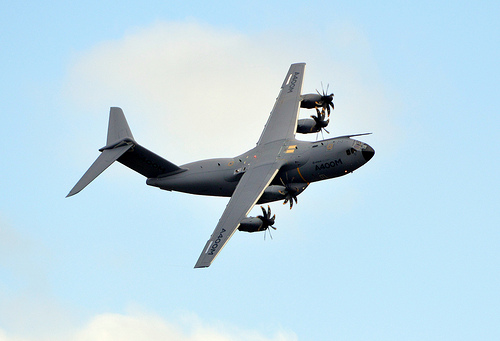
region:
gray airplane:
[72, 32, 379, 293]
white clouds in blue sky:
[21, 16, 105, 70]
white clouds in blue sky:
[4, 88, 64, 125]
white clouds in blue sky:
[24, 221, 104, 262]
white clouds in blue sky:
[87, 206, 161, 261]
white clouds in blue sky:
[70, 273, 172, 327]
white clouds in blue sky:
[227, 261, 324, 328]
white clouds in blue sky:
[324, 281, 372, 313]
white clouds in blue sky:
[362, 238, 454, 319]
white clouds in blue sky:
[324, 193, 424, 244]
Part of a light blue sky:
[10, 288, 51, 338]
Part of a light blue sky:
[68, 280, 105, 330]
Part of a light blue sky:
[156, 279, 202, 337]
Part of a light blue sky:
[226, 291, 296, 326]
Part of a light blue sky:
[305, 274, 352, 338]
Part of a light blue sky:
[359, 264, 404, 310]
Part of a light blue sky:
[421, 266, 478, 338]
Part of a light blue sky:
[396, 213, 466, 260]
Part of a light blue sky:
[319, 204, 379, 262]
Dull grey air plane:
[68, 53, 368, 293]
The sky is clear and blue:
[374, 25, 487, 314]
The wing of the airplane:
[191, 166, 283, 271]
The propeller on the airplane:
[259, 200, 282, 237]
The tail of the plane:
[54, 95, 181, 198]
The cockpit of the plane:
[339, 136, 365, 156]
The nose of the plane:
[335, 131, 379, 171]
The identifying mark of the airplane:
[203, 223, 230, 260]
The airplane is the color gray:
[43, 60, 369, 275]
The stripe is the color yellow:
[291, 163, 316, 195]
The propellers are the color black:
[313, 75, 343, 140]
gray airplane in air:
[82, 60, 388, 284]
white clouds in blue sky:
[15, 148, 43, 196]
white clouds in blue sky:
[286, 253, 342, 303]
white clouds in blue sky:
[349, 265, 416, 312]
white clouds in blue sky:
[402, 51, 447, 104]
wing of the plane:
[171, 175, 274, 294]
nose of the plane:
[342, 135, 381, 178]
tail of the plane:
[77, 107, 179, 192]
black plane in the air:
[136, 87, 423, 268]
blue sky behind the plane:
[373, 134, 454, 232]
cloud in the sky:
[153, 17, 249, 92]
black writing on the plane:
[303, 150, 352, 181]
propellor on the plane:
[246, 201, 284, 248]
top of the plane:
[223, 136, 293, 171]